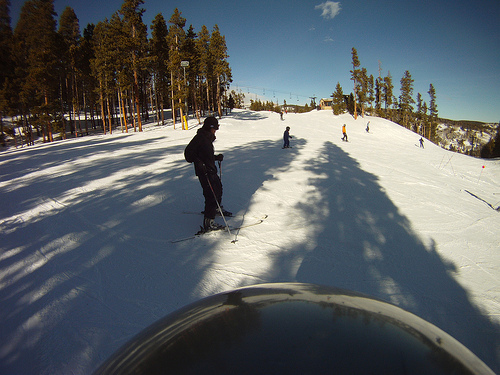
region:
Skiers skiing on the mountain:
[166, 119, 426, 251]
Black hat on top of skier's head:
[202, 115, 219, 132]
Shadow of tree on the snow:
[239, 138, 496, 373]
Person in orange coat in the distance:
[340, 121, 348, 142]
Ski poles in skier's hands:
[196, 153, 241, 245]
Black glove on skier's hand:
[216, 153, 223, 161]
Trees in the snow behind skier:
[3, 3, 233, 149]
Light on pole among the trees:
[178, 59, 190, 126]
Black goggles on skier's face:
[210, 122, 220, 129]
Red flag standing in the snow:
[477, 163, 486, 180]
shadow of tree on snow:
[315, 138, 403, 293]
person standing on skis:
[183, 125, 257, 260]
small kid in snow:
[273, 126, 300, 156]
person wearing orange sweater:
[334, 118, 370, 170]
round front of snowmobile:
[271, 280, 322, 322]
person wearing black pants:
[193, 170, 244, 219]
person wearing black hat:
[205, 117, 216, 122]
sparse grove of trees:
[351, 74, 421, 141]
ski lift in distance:
[235, 68, 297, 108]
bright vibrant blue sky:
[448, 61, 478, 106]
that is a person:
[191, 107, 219, 232]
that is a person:
[276, 125, 296, 140]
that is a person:
[340, 116, 350, 141]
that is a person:
[360, 120, 377, 130]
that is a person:
[415, 130, 435, 145]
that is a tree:
[165, 45, 170, 115]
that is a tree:
[130, 30, 145, 121]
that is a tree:
[100, 40, 110, 130]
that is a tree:
[70, 57, 76, 153]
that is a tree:
[349, 45, 361, 112]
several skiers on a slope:
[180, 104, 455, 266]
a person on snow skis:
[172, 106, 275, 252]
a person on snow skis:
[279, 124, 293, 151]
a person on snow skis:
[336, 120, 354, 146]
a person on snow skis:
[362, 120, 376, 136]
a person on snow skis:
[413, 134, 428, 151]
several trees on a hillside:
[328, 45, 445, 136]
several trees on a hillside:
[0, 4, 196, 138]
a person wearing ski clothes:
[174, 108, 248, 241]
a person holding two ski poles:
[178, 112, 249, 254]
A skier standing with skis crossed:
[170, 116, 270, 241]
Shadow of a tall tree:
[235, 140, 498, 373]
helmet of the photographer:
[82, 278, 498, 373]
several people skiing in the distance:
[277, 110, 424, 148]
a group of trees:
[0, 0, 232, 148]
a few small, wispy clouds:
[305, 0, 340, 45]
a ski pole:
[200, 166, 235, 241]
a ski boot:
[194, 220, 224, 236]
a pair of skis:
[169, 210, 262, 243]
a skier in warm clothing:
[183, 115, 226, 232]